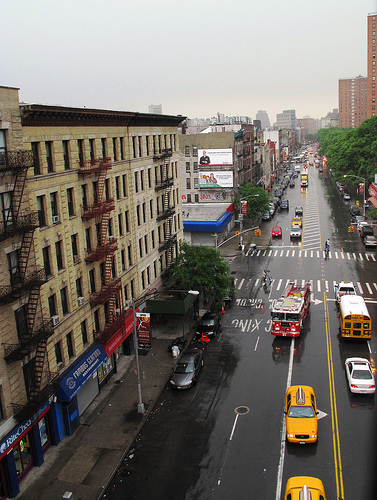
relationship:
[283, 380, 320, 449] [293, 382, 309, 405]
cab has sign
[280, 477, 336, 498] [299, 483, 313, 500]
cab has sign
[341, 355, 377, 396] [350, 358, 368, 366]
car has sun roof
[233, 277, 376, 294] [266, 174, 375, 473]
cross walk on street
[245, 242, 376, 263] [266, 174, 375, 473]
cross walk on street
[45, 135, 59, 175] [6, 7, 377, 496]
window in photo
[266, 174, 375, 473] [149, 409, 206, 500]
street has tarmac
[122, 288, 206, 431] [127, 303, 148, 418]
light has pole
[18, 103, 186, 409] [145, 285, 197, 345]
apartments have canopy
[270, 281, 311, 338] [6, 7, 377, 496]
fire truck in photo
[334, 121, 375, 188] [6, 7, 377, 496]
tree in photo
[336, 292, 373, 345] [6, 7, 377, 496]
school bus in photo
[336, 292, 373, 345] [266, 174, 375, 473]
school bus on street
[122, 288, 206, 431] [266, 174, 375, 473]
light on street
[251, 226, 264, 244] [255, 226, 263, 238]
traffic light on red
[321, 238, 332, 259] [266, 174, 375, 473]
person crossing street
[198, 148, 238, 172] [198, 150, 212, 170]
billboard has people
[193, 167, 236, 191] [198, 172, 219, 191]
billboard has people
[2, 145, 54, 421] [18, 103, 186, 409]
fire escape on apartments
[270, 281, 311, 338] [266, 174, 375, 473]
fire truck on street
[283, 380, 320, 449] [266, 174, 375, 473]
cab on street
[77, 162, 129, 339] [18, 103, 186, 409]
fire escape on apartments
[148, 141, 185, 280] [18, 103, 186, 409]
fire escape on apartments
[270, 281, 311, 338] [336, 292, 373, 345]
fire truck next to school bus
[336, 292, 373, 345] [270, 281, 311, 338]
school bus next to fire truck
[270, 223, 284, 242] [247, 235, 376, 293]
car at intersection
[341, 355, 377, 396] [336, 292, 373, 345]
car behind school bus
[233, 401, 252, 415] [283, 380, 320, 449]
manhole next to cab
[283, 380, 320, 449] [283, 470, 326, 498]
cab behind cab